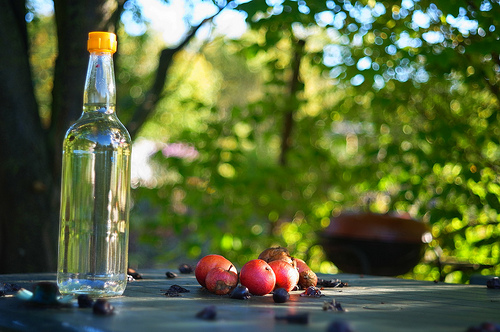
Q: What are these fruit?
A: Apples.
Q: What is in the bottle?
A: Nothing.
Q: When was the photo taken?
A: During the daytime.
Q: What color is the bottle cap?
A: Yellow.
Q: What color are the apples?
A: Red.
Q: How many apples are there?
A: Four.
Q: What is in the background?
A: A grill.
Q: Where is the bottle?
A: On the table.